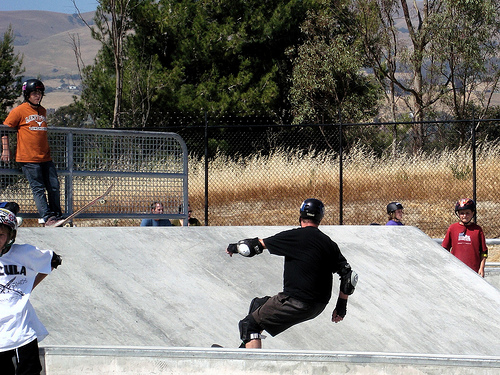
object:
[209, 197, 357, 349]
skater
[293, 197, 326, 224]
helmets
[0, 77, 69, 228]
skater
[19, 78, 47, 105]
helmets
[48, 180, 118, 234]
skate board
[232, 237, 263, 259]
elbow pads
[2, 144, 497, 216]
grass area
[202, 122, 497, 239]
fence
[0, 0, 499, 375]
background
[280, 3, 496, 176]
trees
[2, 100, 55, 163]
orange shirt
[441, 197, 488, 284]
boy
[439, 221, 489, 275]
red shirt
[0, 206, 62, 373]
man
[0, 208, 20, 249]
blue helmet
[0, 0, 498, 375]
in photo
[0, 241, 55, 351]
white shirt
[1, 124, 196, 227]
fence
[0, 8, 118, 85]
mountains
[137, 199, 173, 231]
people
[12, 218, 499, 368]
skating ramp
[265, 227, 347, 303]
black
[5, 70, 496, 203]
area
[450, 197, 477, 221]
helmet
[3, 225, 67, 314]
back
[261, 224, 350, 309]
black shirt